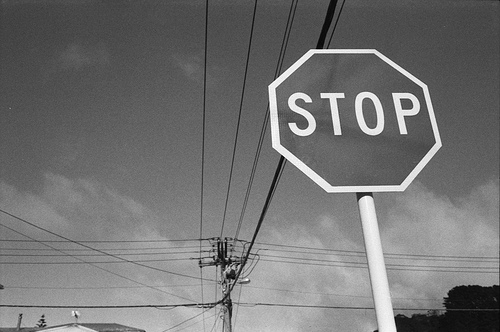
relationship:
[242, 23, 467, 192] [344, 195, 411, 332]
sign on pole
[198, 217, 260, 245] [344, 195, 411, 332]
wires on pole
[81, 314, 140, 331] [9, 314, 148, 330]
roof on house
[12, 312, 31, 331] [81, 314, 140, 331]
chimney on roof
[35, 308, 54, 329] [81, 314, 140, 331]
tree above roof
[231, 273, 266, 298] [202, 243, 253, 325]
light on pole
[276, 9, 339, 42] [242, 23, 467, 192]
lines above sign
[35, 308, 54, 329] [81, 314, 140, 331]
tree behind roof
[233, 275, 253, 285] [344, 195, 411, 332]
light on pole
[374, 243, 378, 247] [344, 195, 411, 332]
part of post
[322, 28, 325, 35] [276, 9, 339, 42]
edge of lines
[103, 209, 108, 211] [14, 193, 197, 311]
part of cloud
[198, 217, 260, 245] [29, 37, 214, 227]
wires in sky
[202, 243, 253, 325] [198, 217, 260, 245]
pole connected to wires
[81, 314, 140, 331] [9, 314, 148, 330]
roof of house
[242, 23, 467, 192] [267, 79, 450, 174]
sign says stop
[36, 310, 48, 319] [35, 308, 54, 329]
top of tree